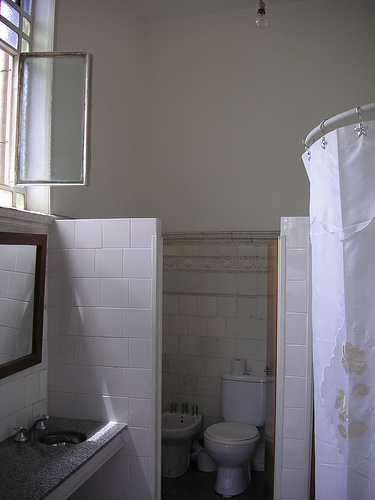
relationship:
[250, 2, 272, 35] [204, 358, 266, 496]
light above toilet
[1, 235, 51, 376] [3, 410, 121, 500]
mirror above sink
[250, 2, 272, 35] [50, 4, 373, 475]
light near wall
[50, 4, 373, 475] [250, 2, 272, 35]
wall near light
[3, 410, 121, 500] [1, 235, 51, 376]
sink below mirror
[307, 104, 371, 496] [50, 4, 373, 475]
curtains near wall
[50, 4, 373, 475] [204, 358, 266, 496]
wall behind toilet